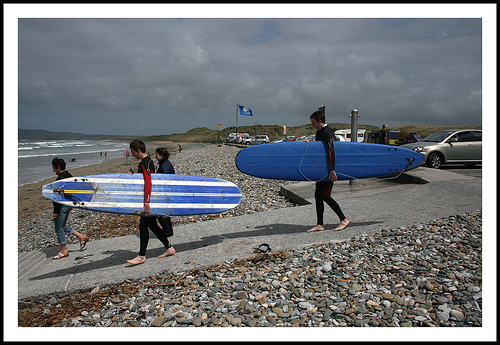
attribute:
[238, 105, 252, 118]
flag — blue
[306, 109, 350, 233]
man — standing, walking, surfer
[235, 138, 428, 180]
surfboard — blue, long, white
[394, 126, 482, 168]
car — parked, silver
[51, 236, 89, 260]
sandals — white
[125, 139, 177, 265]
man — walking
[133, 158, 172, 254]
wet suit — black, red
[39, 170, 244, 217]
surfboard — blue, white, striped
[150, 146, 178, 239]
woman — walking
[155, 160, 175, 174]
shirt — blue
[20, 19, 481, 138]
sky — cloudy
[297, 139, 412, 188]
leash — white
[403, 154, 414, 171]
leash holder — black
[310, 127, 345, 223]
wet suit — black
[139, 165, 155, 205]
sleeve — red